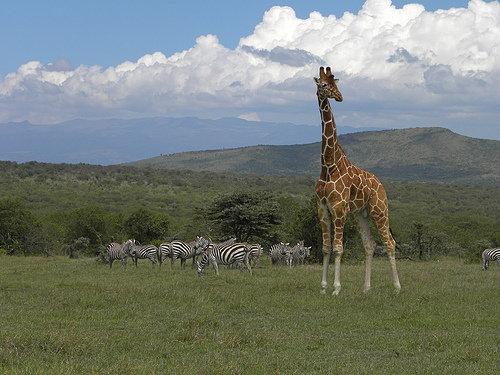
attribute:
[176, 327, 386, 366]
grass — growing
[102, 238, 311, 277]
zebras — striped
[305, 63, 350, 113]
horns — girrafe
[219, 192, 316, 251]
tree — growing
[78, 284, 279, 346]
field — open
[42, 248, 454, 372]
field — grassy 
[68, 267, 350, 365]
grass — short, green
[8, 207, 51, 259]
tree — green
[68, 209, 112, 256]
tree — green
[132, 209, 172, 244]
tree — green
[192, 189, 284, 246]
tree — green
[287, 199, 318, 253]
tree — green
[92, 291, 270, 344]
grass — green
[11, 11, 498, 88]
clouds — thick, white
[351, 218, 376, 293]
leg — hind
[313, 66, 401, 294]
giraffe — yellow, black, standing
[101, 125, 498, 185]
mountain — tall, brown, green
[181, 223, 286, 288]
zebra — white, black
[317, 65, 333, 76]
horns — tiny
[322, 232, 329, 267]
leg — white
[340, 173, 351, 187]
spot — brown, white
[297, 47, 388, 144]
head — its